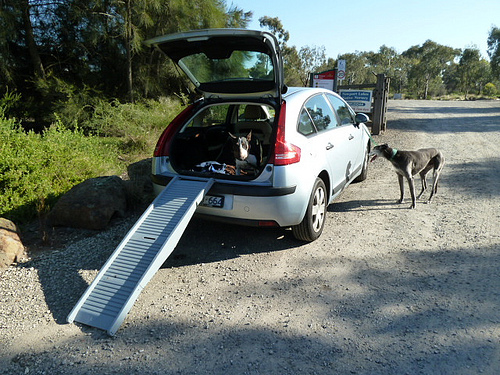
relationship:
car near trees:
[140, 23, 378, 253] [1, 0, 178, 104]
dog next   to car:
[368, 141, 449, 209] [140, 23, 378, 253]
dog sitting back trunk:
[218, 125, 263, 182] [180, 113, 268, 183]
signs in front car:
[320, 58, 378, 111] [140, 23, 378, 253]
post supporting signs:
[369, 69, 390, 134] [320, 58, 378, 111]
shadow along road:
[211, 238, 479, 357] [363, 104, 490, 374]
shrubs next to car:
[6, 96, 141, 220] [140, 23, 378, 253]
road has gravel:
[363, 104, 490, 374] [406, 214, 480, 361]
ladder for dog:
[55, 169, 216, 344] [368, 141, 449, 209]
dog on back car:
[218, 125, 263, 182] [161, 85, 282, 199]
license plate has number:
[195, 193, 228, 213] [201, 193, 222, 208]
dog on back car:
[218, 125, 263, 182] [140, 23, 378, 253]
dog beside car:
[368, 141, 449, 209] [140, 23, 378, 253]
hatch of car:
[132, 20, 302, 187] [140, 23, 378, 253]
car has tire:
[140, 23, 378, 253] [298, 173, 332, 246]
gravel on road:
[406, 214, 480, 361] [1, 98, 500, 374]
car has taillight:
[140, 23, 378, 253] [270, 135, 304, 168]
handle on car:
[323, 141, 338, 151] [140, 23, 378, 253]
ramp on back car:
[55, 169, 216, 344] [140, 23, 378, 253]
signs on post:
[336, 88, 372, 112] [370, 72, 385, 134]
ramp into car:
[55, 169, 216, 344] [140, 23, 378, 253]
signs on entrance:
[336, 88, 372, 112] [315, 66, 486, 113]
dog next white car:
[368, 141, 449, 209] [140, 23, 378, 253]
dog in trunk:
[218, 125, 263, 182] [180, 113, 268, 183]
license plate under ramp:
[195, 193, 228, 213] [55, 169, 216, 344]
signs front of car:
[336, 88, 372, 112] [140, 23, 378, 253]